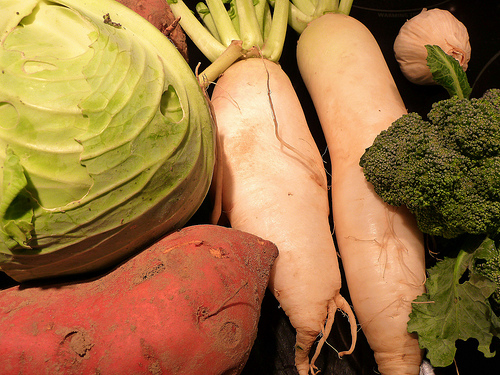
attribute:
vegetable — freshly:
[2, 2, 499, 373]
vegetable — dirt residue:
[0, 222, 279, 372]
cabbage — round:
[6, 10, 227, 265]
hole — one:
[150, 74, 202, 121]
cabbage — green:
[6, 33, 233, 233]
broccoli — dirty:
[344, 99, 481, 230]